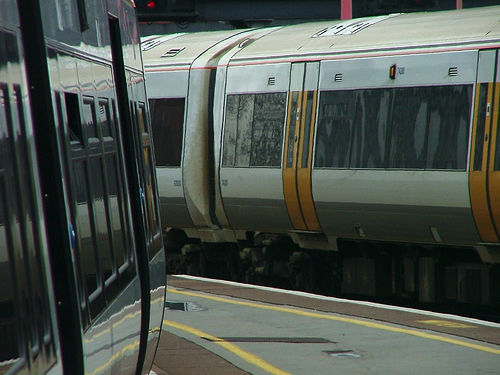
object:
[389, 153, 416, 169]
part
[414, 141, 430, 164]
part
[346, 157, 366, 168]
part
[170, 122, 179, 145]
part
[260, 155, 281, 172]
part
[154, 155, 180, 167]
part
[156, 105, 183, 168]
window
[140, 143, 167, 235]
window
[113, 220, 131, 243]
part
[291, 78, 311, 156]
yellow door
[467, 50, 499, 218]
yellow door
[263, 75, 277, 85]
small vent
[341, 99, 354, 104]
small vent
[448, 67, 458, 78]
small vent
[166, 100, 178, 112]
small vent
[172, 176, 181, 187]
small vent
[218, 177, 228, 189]
small vent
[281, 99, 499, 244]
2 sets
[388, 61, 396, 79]
light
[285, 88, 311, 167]
window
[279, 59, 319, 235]
door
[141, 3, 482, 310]
train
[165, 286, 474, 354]
line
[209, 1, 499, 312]
car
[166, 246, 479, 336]
tracks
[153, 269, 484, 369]
walkway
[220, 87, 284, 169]
window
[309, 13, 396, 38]
mark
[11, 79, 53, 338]
windows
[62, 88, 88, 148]
window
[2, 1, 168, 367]
train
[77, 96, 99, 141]
window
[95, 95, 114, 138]
window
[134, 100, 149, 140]
window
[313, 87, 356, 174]
window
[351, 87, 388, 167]
window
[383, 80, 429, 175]
window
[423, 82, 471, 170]
window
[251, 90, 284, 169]
window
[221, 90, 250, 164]
window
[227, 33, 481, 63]
stripes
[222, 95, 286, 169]
window